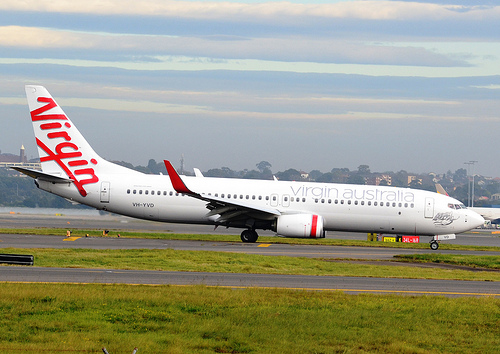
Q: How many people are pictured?
A: 0.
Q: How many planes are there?
A: 1.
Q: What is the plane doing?
A: Getting ready to leave.